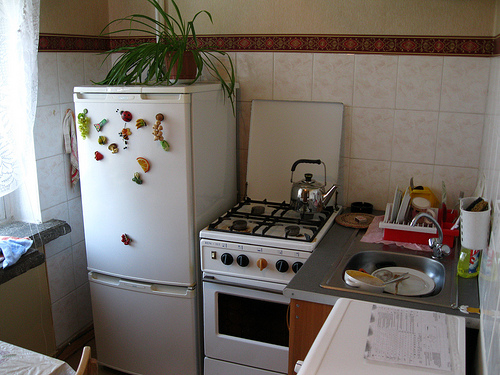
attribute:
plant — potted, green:
[94, 1, 243, 115]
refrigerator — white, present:
[72, 81, 239, 373]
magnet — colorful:
[121, 232, 134, 249]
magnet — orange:
[136, 156, 152, 174]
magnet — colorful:
[94, 152, 105, 163]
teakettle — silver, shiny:
[290, 158, 339, 216]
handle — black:
[290, 157, 329, 188]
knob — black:
[220, 252, 235, 266]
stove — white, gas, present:
[200, 197, 345, 374]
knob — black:
[236, 253, 252, 268]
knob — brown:
[256, 256, 269, 272]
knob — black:
[274, 257, 291, 273]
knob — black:
[291, 261, 305, 273]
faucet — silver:
[407, 210, 445, 244]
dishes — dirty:
[344, 266, 438, 296]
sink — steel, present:
[340, 247, 446, 298]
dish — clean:
[397, 186, 414, 225]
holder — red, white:
[378, 203, 460, 249]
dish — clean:
[390, 187, 401, 226]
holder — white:
[457, 194, 493, 252]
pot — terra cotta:
[162, 53, 196, 83]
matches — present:
[354, 213, 368, 224]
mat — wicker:
[336, 210, 376, 229]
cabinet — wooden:
[287, 298, 333, 374]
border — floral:
[112, 32, 500, 59]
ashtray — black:
[350, 198, 373, 213]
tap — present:
[408, 213, 455, 262]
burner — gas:
[209, 214, 263, 238]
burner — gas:
[262, 218, 320, 244]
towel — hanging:
[60, 107, 78, 186]